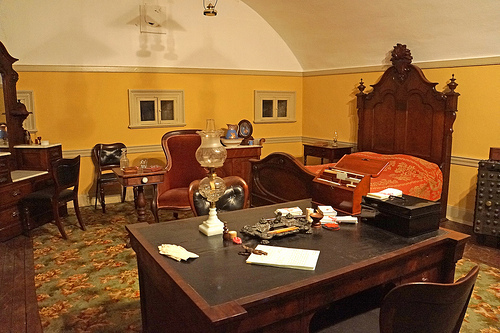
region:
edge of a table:
[272, 246, 278, 259]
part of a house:
[300, 145, 302, 157]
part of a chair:
[404, 282, 409, 287]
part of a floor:
[466, 298, 476, 306]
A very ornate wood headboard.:
[342, 23, 464, 150]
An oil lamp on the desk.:
[190, 108, 239, 240]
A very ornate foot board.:
[242, 142, 314, 213]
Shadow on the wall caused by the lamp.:
[112, 9, 181, 58]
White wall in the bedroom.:
[32, 6, 101, 59]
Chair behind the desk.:
[369, 245, 489, 332]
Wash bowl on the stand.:
[219, 120, 251, 151]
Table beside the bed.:
[297, 135, 357, 167]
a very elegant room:
[39, 18, 483, 330]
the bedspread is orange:
[316, 145, 443, 182]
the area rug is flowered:
[55, 235, 102, 320]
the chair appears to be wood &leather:
[80, 134, 138, 197]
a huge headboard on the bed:
[358, 56, 473, 171]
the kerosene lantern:
[195, 103, 236, 243]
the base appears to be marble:
[191, 123, 226, 248]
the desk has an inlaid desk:
[138, 197, 463, 327]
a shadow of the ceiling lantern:
[136, 8, 186, 66]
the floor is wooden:
[3, 255, 34, 320]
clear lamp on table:
[170, 123, 237, 215]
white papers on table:
[223, 227, 325, 294]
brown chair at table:
[395, 244, 490, 331]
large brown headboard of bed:
[348, 66, 469, 162]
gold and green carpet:
[63, 234, 123, 313]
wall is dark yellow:
[67, 79, 119, 140]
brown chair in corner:
[0, 108, 74, 206]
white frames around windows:
[113, 86, 195, 123]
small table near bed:
[305, 124, 359, 153]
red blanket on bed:
[293, 147, 449, 197]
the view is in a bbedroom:
[117, 61, 419, 310]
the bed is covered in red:
[313, 129, 434, 191]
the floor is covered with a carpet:
[60, 262, 116, 332]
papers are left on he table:
[202, 183, 304, 270]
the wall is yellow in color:
[84, 75, 101, 124]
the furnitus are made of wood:
[18, 127, 83, 219]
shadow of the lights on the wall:
[135, 12, 189, 47]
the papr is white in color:
[259, 244, 320, 279]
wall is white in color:
[229, 24, 262, 52]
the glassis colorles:
[185, 127, 247, 199]